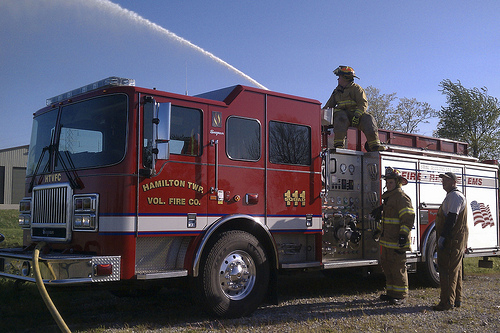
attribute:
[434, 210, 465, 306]
pants — black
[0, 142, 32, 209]
building — metal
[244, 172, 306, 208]
numbers — grey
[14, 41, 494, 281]
truck — large, red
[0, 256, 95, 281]
surface — shiny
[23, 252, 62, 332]
pipe — yellow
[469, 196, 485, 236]
flag — american 